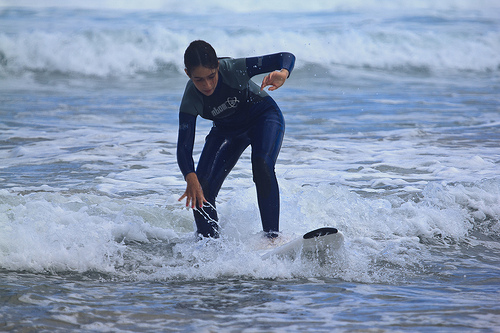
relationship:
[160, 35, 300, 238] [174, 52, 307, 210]
woman has two arms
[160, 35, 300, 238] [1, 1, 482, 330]
woman in water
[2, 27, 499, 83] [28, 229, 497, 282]
waves in background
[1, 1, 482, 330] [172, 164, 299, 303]
blue waters for surfing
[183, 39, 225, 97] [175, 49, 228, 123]
head of a woman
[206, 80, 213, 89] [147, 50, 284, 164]
nose of a woman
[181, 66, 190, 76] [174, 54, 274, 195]
ear of a woman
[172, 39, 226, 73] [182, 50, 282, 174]
hair of a woman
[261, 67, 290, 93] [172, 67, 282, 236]
hand of a woman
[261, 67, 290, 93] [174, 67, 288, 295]
hand of a woman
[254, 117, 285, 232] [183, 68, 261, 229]
leg of a woman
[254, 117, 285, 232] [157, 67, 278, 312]
leg of a woman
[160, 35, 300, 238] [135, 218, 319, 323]
woman on a surfboard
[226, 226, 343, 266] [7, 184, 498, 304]
surfboard in water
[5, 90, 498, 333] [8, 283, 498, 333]
waves coming towards shore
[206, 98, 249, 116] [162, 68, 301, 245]
white logo on a wetsuit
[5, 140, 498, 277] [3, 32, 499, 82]
waves white waves waves are white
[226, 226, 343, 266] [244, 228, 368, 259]
surfboard board on waves board on waves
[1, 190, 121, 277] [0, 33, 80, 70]
white froth froth from waves waves froth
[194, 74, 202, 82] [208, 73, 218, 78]
eye woman eye eye of woman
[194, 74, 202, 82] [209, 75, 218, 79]
eye woman eye eye of a woman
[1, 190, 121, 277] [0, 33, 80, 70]
foamy water foamy salt water salt water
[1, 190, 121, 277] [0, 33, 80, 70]
frothy sea foam sea foam waves white foam waves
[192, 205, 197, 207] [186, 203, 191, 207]
orange nail polish red nail polish nail polish